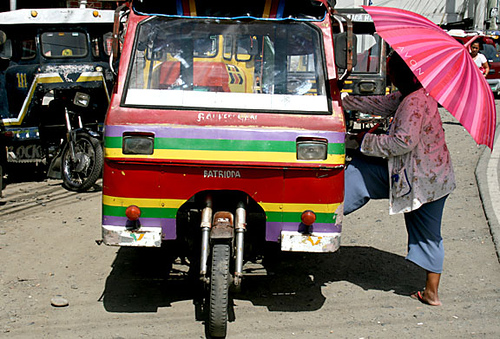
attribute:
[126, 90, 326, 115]
stripe — bright white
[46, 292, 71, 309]
rock — round, small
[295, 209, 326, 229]
turn signal — round, small, red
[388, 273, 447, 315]
flip flop — bright pink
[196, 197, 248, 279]
shock absorbers — metal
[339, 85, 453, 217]
sweater — flower pattern, white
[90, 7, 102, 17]
light — yellow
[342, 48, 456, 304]
woman — striped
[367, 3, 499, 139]
umbrella — pink, striped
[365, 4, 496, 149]
umbrella — pink, striped, purple, bright pink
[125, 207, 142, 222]
light — red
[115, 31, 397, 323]
cab — motor cab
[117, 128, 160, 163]
light — yellow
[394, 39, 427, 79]
letters — pink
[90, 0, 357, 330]
vehicle — multi colored